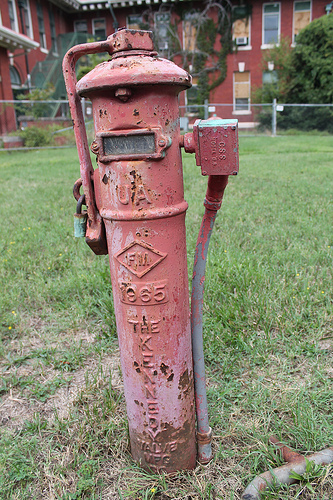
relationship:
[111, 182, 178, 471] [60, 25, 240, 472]
lettering on fire hydrant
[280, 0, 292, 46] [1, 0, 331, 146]
wall of building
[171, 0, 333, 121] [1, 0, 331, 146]
wall of building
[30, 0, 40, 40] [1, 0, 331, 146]
wall of building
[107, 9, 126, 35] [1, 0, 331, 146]
wall of building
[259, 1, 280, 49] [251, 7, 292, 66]
trim of window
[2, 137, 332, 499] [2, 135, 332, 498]
grass of ground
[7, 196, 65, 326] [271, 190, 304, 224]
flowers growing on ground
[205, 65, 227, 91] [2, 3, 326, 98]
vines on building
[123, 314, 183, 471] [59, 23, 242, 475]
manufacturer identification on utility box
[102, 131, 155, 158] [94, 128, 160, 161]
information window on box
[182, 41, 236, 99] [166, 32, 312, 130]
vines growing on wall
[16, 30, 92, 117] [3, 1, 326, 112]
stairway to building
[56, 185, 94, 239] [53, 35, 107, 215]
lock on lever